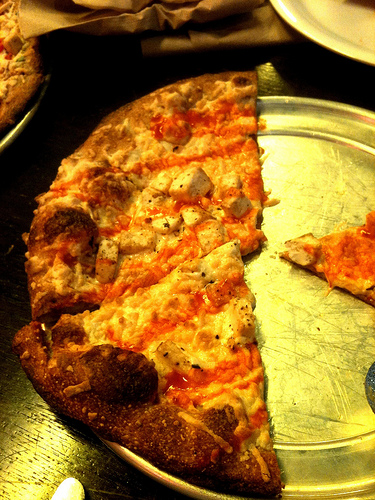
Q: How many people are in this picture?
A: 0.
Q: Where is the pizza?
A: On the tray.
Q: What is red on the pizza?
A: Sauce.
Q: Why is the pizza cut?
A: To make slices.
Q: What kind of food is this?
A: Italian.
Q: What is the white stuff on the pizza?
A: Cheese.